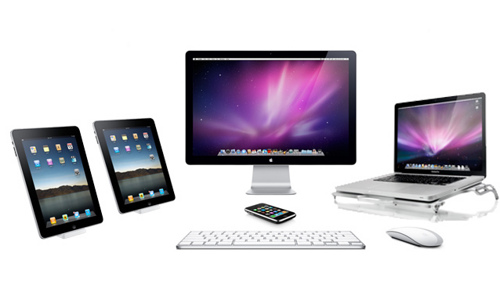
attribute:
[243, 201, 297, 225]
apple iphone — black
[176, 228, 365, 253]
keyboard — white, thin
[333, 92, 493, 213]
computer — open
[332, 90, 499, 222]
laptop — light, colored, Apple MacBook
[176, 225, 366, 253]
device — electronic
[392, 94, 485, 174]
screen — purple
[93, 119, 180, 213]
ipad tablet — Apple 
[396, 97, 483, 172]
wallpaper — leopard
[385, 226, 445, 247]
mouse — white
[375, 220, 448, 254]
mouse — Apple Magic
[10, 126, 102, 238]
device — electronic